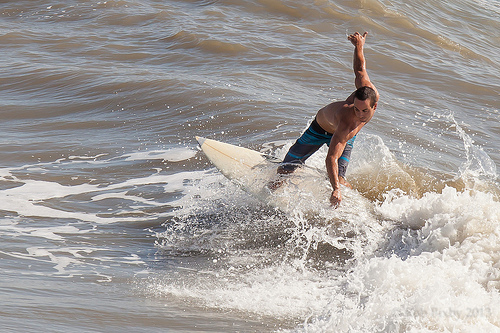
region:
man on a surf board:
[195, 30, 377, 224]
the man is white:
[267, 30, 379, 203]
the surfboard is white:
[194, 135, 369, 213]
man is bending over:
[267, 31, 377, 208]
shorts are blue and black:
[287, 119, 355, 174]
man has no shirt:
[316, 84, 378, 139]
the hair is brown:
[351, 86, 376, 106]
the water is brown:
[1, 0, 498, 331]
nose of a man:
[357, 109, 362, 117]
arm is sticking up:
[350, 31, 371, 86]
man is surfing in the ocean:
[182, 30, 401, 285]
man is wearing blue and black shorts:
[284, 116, 330, 181]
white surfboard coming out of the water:
[179, 125, 267, 190]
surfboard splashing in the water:
[366, 197, 474, 325]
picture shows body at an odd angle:
[314, 8, 388, 202]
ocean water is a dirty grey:
[37, 22, 212, 138]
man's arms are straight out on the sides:
[322, 8, 382, 213]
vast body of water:
[24, 31, 191, 144]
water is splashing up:
[251, 168, 319, 262]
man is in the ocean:
[294, 20, 399, 225]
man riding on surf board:
[197, 41, 408, 228]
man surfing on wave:
[180, 39, 414, 243]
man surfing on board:
[200, 19, 411, 260]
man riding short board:
[165, 22, 406, 244]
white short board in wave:
[204, 139, 388, 239]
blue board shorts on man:
[287, 131, 362, 181]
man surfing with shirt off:
[265, 31, 395, 219]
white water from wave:
[317, 241, 468, 332]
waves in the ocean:
[47, 66, 219, 170]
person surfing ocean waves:
[175, 34, 434, 239]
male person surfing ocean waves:
[177, 33, 427, 258]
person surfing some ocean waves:
[191, 28, 414, 226]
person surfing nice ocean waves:
[201, 31, 403, 225]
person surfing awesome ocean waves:
[209, 80, 406, 264]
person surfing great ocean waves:
[183, 80, 403, 248]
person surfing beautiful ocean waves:
[213, 80, 419, 234]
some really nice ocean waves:
[331, 187, 471, 296]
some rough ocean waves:
[340, 165, 485, 297]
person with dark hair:
[342, 81, 380, 131]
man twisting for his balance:
[261, 30, 378, 207]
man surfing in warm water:
[262, 29, 376, 208]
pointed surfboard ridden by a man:
[192, 135, 384, 237]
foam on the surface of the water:
[2, 139, 231, 283]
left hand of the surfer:
[348, 29, 368, 44]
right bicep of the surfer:
[335, 140, 347, 159]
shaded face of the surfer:
[352, 97, 369, 125]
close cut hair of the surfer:
[350, 85, 375, 107]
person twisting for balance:
[262, 30, 377, 207]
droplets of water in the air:
[395, 105, 446, 158]